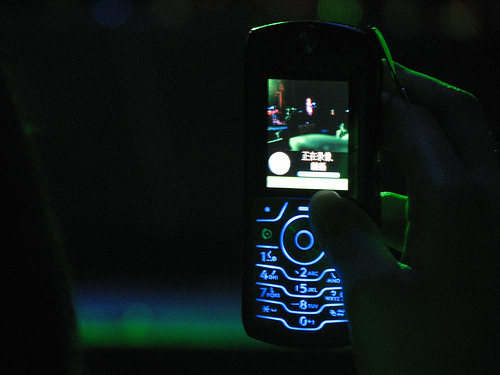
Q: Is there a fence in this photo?
A: No, there are no fences.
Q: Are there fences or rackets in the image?
A: No, there are no fences or rackets.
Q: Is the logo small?
A: Yes, the logo is small.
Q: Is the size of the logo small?
A: Yes, the logo is small.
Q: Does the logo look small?
A: Yes, the logo is small.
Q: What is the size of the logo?
A: The logo is small.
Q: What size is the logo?
A: The logo is small.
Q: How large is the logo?
A: The logo is small.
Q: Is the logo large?
A: No, the logo is small.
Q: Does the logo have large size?
A: No, the logo is small.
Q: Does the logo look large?
A: No, the logo is small.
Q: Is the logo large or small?
A: The logo is small.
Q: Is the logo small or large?
A: The logo is small.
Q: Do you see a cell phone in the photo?
A: Yes, there is a cell phone.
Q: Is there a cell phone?
A: Yes, there is a cell phone.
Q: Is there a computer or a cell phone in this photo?
A: Yes, there is a cell phone.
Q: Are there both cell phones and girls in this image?
A: No, there is a cell phone but no girls.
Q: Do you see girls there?
A: No, there are no girls.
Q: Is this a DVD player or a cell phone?
A: This is a cell phone.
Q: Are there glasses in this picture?
A: No, there are no glasses.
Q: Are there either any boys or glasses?
A: No, there are no glasses or boys.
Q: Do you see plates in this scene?
A: No, there are no plates.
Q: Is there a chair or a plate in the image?
A: No, there are no plates or chairs.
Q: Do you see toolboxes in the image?
A: No, there are no toolboxes.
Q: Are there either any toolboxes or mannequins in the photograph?
A: No, there are no toolboxes or mannequins.